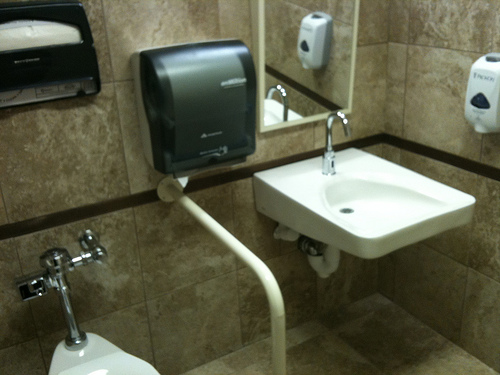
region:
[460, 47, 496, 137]
White soap container attached to wall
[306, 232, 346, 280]
U pipe under sink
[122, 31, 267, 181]
Black paper towel holder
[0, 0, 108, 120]
Black container for seat cover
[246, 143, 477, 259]
White sink attached to the wall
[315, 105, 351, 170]
Faucet attached to white sink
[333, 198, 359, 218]
Drain in white sink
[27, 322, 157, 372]
Back of white toliet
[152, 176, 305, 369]
Handicap bar attached to wall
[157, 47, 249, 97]
Paper towel inside container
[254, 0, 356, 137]
Mirror above white sink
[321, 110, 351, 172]
Silver faucet on white sink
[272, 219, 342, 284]
White pipe below white sink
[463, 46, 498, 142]
Hand soap dispenser near sink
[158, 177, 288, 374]
Beige railing below towel dispenser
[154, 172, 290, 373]
Beige railing near white pipe under sink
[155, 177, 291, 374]
Beige railing next to white sink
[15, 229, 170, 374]
Toilet below toilet seat cover dispenser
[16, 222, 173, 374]
Toilet next to beige rail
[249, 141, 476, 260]
White sink is square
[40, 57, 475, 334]
A public bathroom with brown tiled floors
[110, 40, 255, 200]
Container that holds paper towels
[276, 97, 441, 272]
A handicapped-approved sink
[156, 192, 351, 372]
A white railing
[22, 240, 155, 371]
The toilet area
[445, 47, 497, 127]
The soap dispenser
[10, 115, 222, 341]
Brown tiled bathroom walls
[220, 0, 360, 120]
Mirror above sink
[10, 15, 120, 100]
A dispenser holding toilet seat covers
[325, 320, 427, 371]
Brown tiled floor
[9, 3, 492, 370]
A public restroom scene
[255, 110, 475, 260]
This is the restroom sink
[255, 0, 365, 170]
A mirror is above the sink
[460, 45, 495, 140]
A hand soap dispenser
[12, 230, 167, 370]
This is an automatic flush toilet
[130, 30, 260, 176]
A paper towel dispenser is on the wall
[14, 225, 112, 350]
The toilet's plumbing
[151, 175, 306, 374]
A handicapped assistance bar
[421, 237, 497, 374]
The wall and floor is tiled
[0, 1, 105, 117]
A toilet seat cover dispenser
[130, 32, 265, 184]
paper towel dispenser on bathroom wall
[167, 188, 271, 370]
white metal safety rail beside toilet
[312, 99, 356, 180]
silver metal bathroom sink faucet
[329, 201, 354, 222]
silver drain on bathroom sink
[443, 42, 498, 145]
white hand soap dispenser on bathroom wall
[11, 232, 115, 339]
silver metal toiler plumbing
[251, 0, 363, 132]
bathroom mirror with white trim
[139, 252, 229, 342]
brown tile on bathroom wall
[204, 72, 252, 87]
writing on front of paper towel dispenser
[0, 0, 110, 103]
toiler seat cover holder